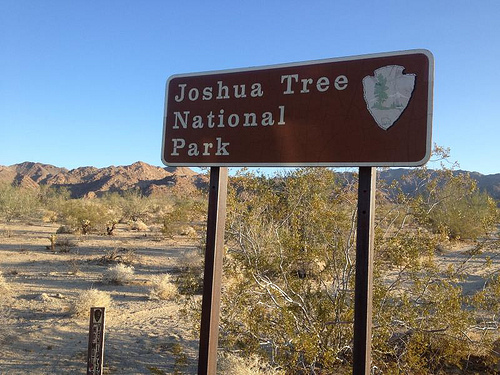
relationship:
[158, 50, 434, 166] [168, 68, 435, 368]
park sign on metal post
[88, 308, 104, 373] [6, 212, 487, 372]
post in ground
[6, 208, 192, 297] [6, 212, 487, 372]
sand on ground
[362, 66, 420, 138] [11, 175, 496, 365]
map of park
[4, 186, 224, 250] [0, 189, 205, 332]
shrubs planted under sand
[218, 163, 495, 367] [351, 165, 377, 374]
tree behind metal post